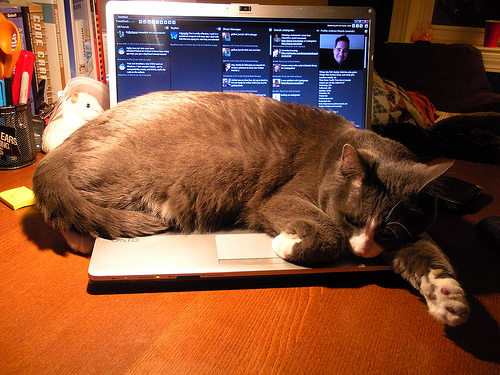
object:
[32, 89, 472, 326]
cat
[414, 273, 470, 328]
paw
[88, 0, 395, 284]
laptop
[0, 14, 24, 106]
scissor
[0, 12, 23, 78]
handles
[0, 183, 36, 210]
post-it notes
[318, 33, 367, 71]
picture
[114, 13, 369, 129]
screen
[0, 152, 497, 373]
wood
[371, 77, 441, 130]
blanket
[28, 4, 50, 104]
books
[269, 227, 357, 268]
paws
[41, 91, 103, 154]
toy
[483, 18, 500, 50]
cup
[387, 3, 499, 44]
window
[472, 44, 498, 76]
sill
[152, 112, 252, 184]
fur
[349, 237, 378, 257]
nose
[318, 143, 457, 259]
head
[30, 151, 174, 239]
tail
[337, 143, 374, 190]
right ear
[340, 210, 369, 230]
eye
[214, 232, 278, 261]
touch pad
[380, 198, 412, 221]
whiskers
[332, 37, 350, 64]
face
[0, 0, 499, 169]
background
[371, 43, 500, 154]
couch